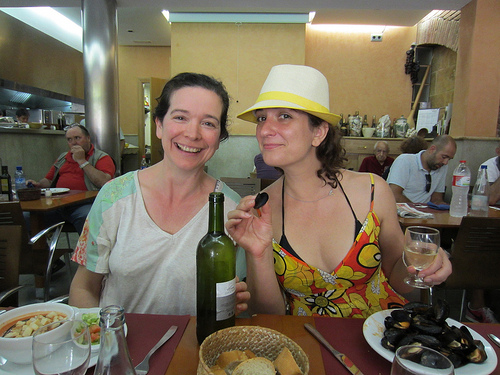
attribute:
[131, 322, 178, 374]
silver fork — metallic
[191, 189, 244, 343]
bottle — green, wine bottle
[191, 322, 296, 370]
bread — sliced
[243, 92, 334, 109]
stripe — yellow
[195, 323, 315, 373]
basket — wicker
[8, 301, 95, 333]
soup — pasta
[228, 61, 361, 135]
hat — white, yellow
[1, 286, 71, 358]
bowl — white, circular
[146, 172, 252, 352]
bottle — large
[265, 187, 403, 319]
dress — colorful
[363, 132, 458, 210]
man — looking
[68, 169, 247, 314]
top — v-necked, loose fitting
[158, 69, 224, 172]
woman — smiling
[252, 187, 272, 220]
bottle — glass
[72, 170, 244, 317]
shirt — white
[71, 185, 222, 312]
shirt — white, pink, green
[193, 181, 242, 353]
wine bottle — green, glass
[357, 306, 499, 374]
plate — full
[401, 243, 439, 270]
wine — white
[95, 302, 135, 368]
bottle — clear, glass, open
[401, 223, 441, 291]
glass — clear, round, short-stemmed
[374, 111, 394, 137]
item — decorative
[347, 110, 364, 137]
item — decorative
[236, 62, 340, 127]
hat — yellow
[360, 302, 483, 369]
plate — white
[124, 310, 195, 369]
placemat — red